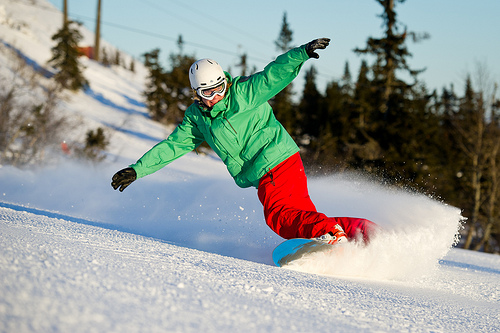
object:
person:
[111, 37, 379, 250]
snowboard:
[270, 236, 370, 266]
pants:
[256, 151, 379, 244]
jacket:
[127, 44, 310, 189]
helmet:
[188, 58, 226, 90]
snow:
[0, 0, 500, 331]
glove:
[111, 167, 139, 192]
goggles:
[199, 76, 233, 101]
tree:
[347, 0, 432, 174]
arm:
[132, 113, 200, 174]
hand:
[303, 37, 331, 60]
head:
[188, 56, 232, 108]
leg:
[256, 156, 336, 239]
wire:
[28, 5, 277, 65]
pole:
[91, 0, 103, 63]